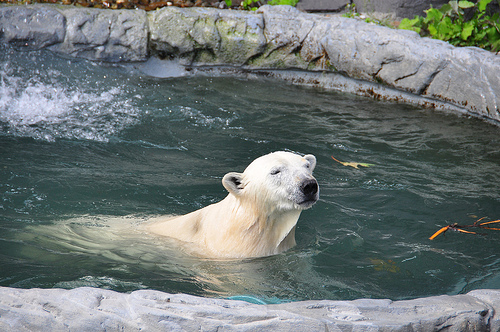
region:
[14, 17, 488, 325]
a polar bear in water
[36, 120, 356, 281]
the polar bear is swimming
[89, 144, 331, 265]
the polar bear is white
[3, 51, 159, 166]
foaming water in the pool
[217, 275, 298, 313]
a light blue object floating near the polar bear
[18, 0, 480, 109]
the edge of the pool is stone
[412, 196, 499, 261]
an orange item floating in the pool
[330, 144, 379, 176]
a leaf in the pool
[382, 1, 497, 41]
the green tree is near the pond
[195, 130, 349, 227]
the polar bear looks happy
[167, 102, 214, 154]
part of a water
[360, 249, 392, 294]
par of a wave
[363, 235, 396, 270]
part fo a water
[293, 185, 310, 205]
par tof a mouth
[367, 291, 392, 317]
edge of a stone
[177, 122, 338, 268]
polar bear in the water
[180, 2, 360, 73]
man-made stone containment wall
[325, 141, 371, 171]
leaf on the water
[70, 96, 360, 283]
white bear taking a swim in his pool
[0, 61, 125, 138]
churning water in the pool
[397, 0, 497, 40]
foliage on the side of the wall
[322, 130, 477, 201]
dark water of the pool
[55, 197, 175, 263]
bear's body submerged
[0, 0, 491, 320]
zoo animal swimming in a man-made pool of water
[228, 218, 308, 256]
wet fur of the bear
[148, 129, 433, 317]
white bear in water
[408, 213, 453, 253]
orange leaves in water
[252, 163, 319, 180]
closed eyes of polar bear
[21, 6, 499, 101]
rock wall around water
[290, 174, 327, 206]
black nose of white bear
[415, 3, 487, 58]
green leaves on bush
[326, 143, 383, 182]
maple leaf floating in water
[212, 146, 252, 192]
round ear of polar bear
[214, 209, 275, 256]
wet fur of polar bear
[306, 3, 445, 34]
rock wall on outside of tub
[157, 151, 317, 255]
Polar bear in the water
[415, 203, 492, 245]
leaves in the water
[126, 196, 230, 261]
Polar bear in the water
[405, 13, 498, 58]
Leaves near a pool of water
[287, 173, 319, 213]
Polar bear with a black nose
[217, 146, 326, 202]
bear with its ears perked up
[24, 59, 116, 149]
Water splashing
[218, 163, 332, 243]
White polar bear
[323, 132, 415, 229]
Leaves in the water